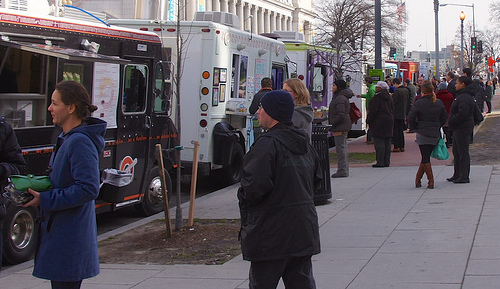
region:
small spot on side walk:
[423, 187, 440, 205]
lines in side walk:
[468, 220, 478, 280]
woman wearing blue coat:
[36, 130, 123, 251]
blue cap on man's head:
[251, 75, 313, 130]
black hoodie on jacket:
[268, 118, 338, 165]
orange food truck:
[383, 46, 437, 95]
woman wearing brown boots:
[397, 146, 452, 193]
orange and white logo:
[99, 142, 147, 199]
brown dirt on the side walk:
[112, 214, 244, 279]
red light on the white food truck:
[181, 50, 216, 102]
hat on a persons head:
[254, 86, 300, 127]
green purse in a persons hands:
[4, 167, 59, 211]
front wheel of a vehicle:
[131, 158, 179, 222]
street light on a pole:
[456, 7, 467, 32]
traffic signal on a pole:
[468, 34, 480, 54]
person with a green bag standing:
[398, 75, 453, 192]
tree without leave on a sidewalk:
[140, 0, 210, 242]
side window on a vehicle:
[225, 47, 252, 108]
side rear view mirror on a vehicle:
[148, 55, 179, 122]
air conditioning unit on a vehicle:
[188, 4, 245, 36]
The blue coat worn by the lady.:
[42, 107, 113, 282]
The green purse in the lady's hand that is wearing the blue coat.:
[8, 165, 49, 192]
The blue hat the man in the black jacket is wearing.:
[258, 89, 297, 124]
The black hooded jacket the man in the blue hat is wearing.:
[236, 121, 333, 256]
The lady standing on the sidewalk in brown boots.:
[403, 81, 444, 205]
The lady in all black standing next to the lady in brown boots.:
[454, 72, 482, 189]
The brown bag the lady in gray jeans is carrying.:
[344, 102, 366, 126]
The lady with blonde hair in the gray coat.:
[285, 77, 322, 131]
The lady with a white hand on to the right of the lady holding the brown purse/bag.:
[371, 77, 396, 169]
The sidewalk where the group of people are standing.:
[247, 85, 499, 285]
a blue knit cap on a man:
[259, 87, 300, 121]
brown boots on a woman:
[409, 157, 442, 190]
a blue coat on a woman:
[22, 114, 110, 277]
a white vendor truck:
[113, 7, 309, 175]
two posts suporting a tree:
[152, 138, 211, 226]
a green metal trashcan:
[301, 107, 341, 210]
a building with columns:
[84, 2, 328, 31]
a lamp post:
[454, 7, 471, 67]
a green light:
[388, 43, 399, 59]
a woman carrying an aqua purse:
[410, 71, 455, 193]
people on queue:
[284, 55, 488, 147]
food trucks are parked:
[27, 15, 437, 215]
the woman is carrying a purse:
[3, 82, 149, 278]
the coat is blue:
[18, 111, 113, 280]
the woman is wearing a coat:
[24, 62, 116, 283]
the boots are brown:
[400, 139, 459, 219]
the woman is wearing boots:
[402, 158, 447, 205]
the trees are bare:
[317, 5, 422, 107]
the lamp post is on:
[452, 10, 472, 79]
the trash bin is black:
[315, 125, 357, 209]